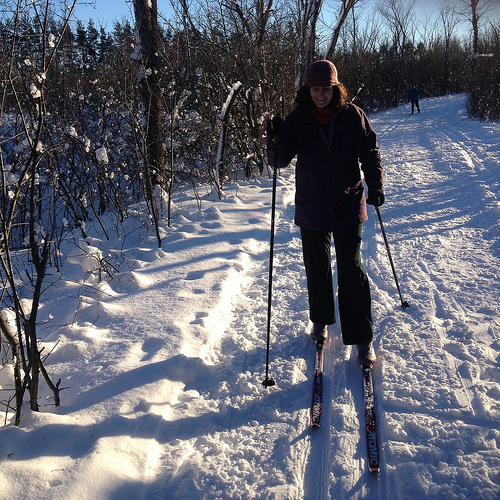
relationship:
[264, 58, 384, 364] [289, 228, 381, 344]
trail has snow pants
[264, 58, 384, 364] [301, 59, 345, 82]
trail has hat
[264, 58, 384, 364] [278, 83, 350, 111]
trail has hair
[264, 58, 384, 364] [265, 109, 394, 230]
trail has snow jacket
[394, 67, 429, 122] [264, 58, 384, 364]
skier behind trail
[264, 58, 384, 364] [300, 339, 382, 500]
trail has skis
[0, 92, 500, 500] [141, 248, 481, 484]
shadow in snow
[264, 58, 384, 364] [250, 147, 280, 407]
trail has pole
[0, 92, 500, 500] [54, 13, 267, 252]
shadow on trees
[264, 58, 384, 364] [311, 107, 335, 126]
trail has scarf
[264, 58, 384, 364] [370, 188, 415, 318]
trail has pole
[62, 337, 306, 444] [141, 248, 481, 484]
shadow on snow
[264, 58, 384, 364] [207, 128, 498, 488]
trail on trail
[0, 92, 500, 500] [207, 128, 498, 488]
shadow on trail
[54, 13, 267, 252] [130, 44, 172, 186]
trees has trunk